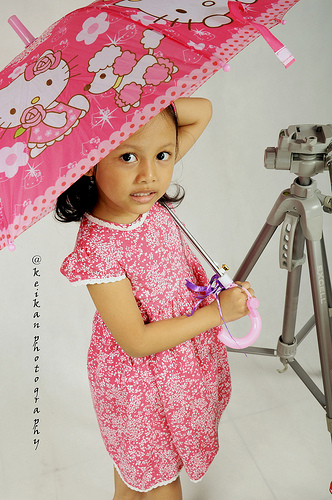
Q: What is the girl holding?
A: An umbrella.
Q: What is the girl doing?
A: Posing.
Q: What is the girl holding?
A: An umbrella.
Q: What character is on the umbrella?
A: Hello kitty.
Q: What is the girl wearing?
A: A pink dress.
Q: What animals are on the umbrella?
A: Cat and dog.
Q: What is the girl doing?
A: Posing for the camera.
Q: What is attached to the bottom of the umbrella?
A: Purple ribbon.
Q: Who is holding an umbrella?
A: A girl.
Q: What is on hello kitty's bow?
A: A flower.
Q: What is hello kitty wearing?
A: A dress.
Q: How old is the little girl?
A: 3 or 4 years old.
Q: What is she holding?
A: An umbrella.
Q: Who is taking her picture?
A: The person holding the camera.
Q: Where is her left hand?
A: Touching her hair.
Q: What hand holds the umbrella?
A: The right hand.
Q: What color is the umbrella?
A: Pink.